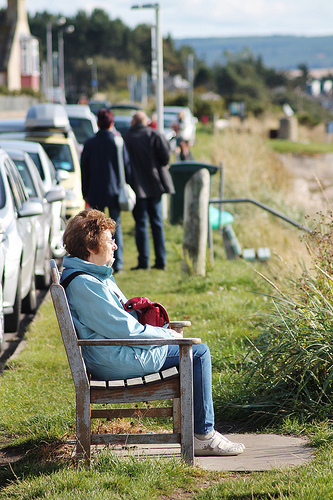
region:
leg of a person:
[150, 200, 182, 263]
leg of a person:
[183, 352, 222, 419]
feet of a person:
[203, 436, 250, 454]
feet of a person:
[130, 262, 156, 273]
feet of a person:
[153, 261, 172, 269]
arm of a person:
[95, 295, 169, 350]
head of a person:
[60, 197, 127, 273]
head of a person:
[89, 102, 128, 132]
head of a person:
[125, 100, 160, 129]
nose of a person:
[107, 238, 123, 254]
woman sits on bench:
[64, 209, 216, 399]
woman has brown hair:
[68, 194, 93, 242]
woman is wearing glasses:
[72, 239, 124, 243]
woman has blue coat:
[56, 256, 153, 370]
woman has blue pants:
[164, 335, 215, 443]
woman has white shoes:
[175, 431, 234, 457]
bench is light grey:
[44, 280, 191, 464]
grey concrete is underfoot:
[177, 427, 327, 486]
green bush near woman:
[204, 239, 329, 395]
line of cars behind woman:
[1, 115, 86, 292]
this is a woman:
[58, 204, 239, 448]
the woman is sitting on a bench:
[42, 210, 250, 449]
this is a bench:
[26, 256, 224, 470]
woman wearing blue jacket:
[55, 245, 173, 393]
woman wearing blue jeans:
[152, 326, 224, 430]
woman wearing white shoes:
[194, 427, 247, 468]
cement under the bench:
[76, 367, 310, 499]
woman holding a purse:
[123, 284, 185, 350]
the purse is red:
[127, 285, 166, 330]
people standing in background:
[77, 95, 212, 271]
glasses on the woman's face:
[99, 236, 117, 246]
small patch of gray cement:
[65, 429, 315, 472]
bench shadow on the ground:
[0, 434, 74, 486]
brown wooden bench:
[46, 257, 202, 470]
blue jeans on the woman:
[164, 341, 216, 433]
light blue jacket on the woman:
[59, 253, 173, 379]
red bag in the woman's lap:
[121, 295, 174, 330]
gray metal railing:
[207, 198, 314, 266]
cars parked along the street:
[0, 95, 195, 343]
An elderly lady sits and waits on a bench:
[40, 200, 247, 469]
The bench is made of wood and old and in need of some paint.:
[45, 262, 202, 466]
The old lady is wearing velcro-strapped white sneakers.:
[187, 431, 245, 459]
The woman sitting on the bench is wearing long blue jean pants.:
[166, 339, 216, 440]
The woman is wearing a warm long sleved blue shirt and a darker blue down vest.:
[56, 255, 171, 380]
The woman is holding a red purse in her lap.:
[122, 295, 172, 328]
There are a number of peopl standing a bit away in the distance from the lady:
[79, 105, 211, 273]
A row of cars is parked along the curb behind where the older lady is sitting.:
[1, 96, 196, 347]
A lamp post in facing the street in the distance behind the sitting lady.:
[128, 0, 168, 137]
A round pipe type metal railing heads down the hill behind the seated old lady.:
[203, 192, 323, 267]